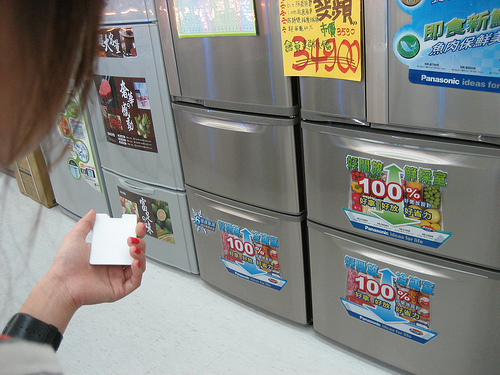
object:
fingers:
[70, 208, 99, 241]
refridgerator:
[75, 1, 201, 279]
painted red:
[127, 236, 142, 246]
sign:
[340, 152, 452, 250]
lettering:
[287, 33, 360, 73]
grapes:
[430, 193, 439, 201]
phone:
[87, 208, 141, 267]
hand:
[47, 203, 152, 306]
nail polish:
[130, 245, 143, 258]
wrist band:
[0, 309, 64, 352]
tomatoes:
[349, 201, 366, 213]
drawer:
[183, 185, 308, 326]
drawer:
[306, 220, 498, 374]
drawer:
[155, 3, 297, 120]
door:
[75, 23, 188, 194]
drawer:
[167, 103, 298, 220]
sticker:
[215, 217, 289, 293]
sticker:
[338, 254, 441, 344]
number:
[381, 180, 405, 203]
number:
[375, 282, 393, 301]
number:
[226, 235, 235, 251]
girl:
[1, 4, 149, 375]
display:
[276, 0, 364, 85]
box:
[361, 0, 499, 148]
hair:
[2, 1, 112, 276]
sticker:
[389, 1, 498, 94]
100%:
[355, 175, 424, 202]